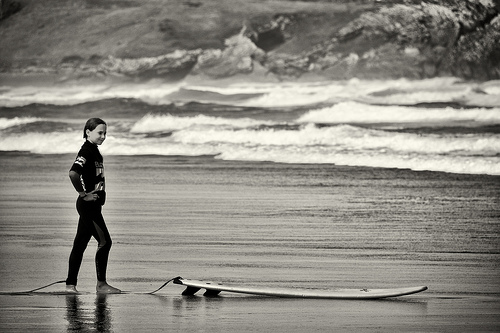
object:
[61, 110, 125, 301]
girl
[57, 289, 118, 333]
shadow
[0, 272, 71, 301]
string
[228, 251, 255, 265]
sand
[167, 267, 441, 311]
surfboard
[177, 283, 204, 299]
fins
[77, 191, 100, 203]
hand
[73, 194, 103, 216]
hips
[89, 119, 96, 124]
black hair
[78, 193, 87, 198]
waist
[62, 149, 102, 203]
right hand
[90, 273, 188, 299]
rope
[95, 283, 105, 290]
right ankle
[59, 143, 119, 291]
wetsuit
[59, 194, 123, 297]
pants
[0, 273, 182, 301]
back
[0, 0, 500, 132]
wave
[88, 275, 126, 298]
feet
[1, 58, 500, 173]
surf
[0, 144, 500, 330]
shore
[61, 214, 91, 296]
leg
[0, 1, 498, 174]
sea